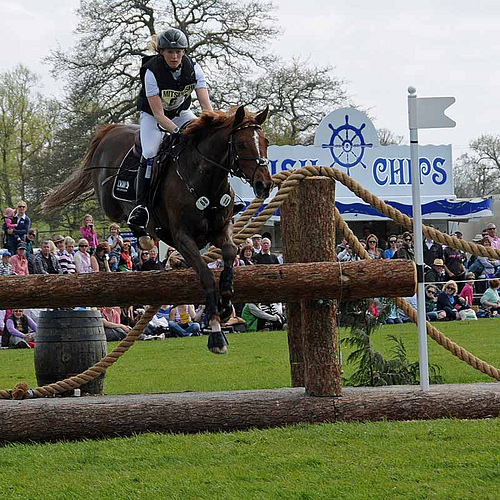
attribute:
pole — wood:
[291, 169, 348, 400]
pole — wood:
[279, 173, 321, 389]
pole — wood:
[0, 257, 425, 309]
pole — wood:
[0, 381, 500, 446]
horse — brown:
[33, 100, 273, 355]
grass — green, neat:
[0, 315, 499, 499]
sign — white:
[212, 107, 460, 203]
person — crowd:
[79, 212, 100, 250]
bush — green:
[339, 242, 449, 393]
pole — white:
[403, 83, 472, 394]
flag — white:
[405, 94, 460, 131]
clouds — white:
[2, 1, 499, 167]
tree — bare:
[19, 0, 273, 235]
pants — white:
[135, 107, 210, 167]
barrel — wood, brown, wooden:
[27, 298, 130, 402]